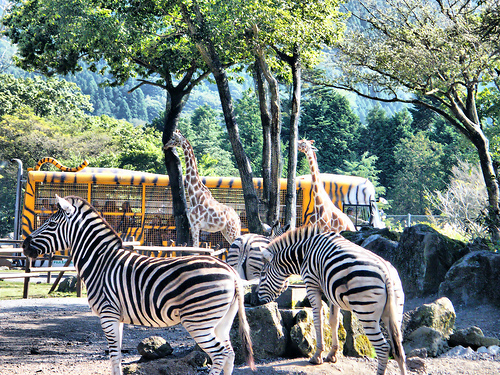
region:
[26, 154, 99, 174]
Yellow and black snake on school bus.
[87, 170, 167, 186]
Tiger stripes on yellow school bus.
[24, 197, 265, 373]
Black and white Zebra in petting zoo.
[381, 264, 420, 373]
Long white Zebra tail.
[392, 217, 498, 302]
Big grey rocks in back of Zebra's.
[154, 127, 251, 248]
Big Giraffe standing by a tree.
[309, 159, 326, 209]
Brown and yellow spots on Giraffe's neck.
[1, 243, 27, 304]
Brown fence in petting zoo.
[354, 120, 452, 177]
Big green trees in back of bus.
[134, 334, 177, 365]
Small egg shaped rock underneath Zebra.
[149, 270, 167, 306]
stripes of a zebra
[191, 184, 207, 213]
spots of a giraffe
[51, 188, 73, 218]
an ear of a zebra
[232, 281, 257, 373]
a tail of a zebra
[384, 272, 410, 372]
a tail of a zebra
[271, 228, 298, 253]
the main of a zebra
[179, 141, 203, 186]
the long neck of a giraffe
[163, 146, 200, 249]
a trunk of a tree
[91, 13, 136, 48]
the leaves of a tree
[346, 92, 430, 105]
a branch of a tree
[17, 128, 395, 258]
A bus in the background.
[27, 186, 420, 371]
Two zebras are near each other.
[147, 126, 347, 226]
Two giraffes are near each other.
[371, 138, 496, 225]
A fence near a tree.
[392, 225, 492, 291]
Some large rocks.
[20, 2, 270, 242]
A tree with leaves on it.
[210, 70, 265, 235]
The trunk of a tree.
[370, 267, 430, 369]
The tail of a zebra.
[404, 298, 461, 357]
A rock next to a zebra.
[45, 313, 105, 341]
A shadow on the ground.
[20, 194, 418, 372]
three zebras near giraffes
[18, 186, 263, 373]
giraffe look to the left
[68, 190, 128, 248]
mane of zebra is white and black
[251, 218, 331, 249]
mane of zebra is black and white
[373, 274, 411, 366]
look tail is long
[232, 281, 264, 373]
long tail of zebra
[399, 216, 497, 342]
big rocks on side of wild and animals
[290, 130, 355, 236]
zebra is licking a tree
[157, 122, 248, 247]
big giraffe next to a tree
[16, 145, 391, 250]
long yellow bus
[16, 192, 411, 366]
three zebras in the zoo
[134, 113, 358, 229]
two giraffes under the trees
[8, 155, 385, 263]
tour bus painted like a tiger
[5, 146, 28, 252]
exhaust pipe on back of bus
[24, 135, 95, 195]
tiger tail on top of bus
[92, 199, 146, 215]
people on the bus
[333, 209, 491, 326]
large rocks in enclosure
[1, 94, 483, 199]
large trees in the distance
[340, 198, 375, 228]
driver of the bus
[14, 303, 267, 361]
shadows of trees on ground